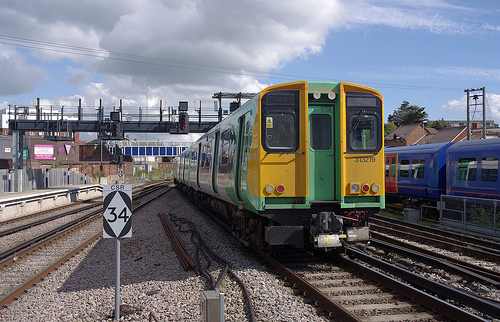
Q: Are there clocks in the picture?
A: No, there are no clocks.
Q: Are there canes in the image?
A: No, there are no canes.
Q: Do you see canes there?
A: No, there are no canes.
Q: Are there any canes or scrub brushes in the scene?
A: No, there are no canes or scrub brushes.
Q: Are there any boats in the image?
A: No, there are no boats.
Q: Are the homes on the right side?
A: Yes, the homes are on the right of the image.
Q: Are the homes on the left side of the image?
A: No, the homes are on the right of the image.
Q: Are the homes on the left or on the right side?
A: The homes are on the right of the image.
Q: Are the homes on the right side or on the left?
A: The homes are on the right of the image.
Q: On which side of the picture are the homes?
A: The homes are on the right of the image.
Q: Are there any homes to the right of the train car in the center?
A: Yes, there are homes to the right of the train car.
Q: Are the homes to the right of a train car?
A: Yes, the homes are to the right of a train car.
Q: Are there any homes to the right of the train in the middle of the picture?
A: Yes, there are homes to the right of the train.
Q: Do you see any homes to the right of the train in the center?
A: Yes, there are homes to the right of the train.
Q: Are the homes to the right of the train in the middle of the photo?
A: Yes, the homes are to the right of the train.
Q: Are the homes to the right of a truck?
A: No, the homes are to the right of the train.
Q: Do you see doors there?
A: Yes, there is a door.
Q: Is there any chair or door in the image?
A: Yes, there is a door.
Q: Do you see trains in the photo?
A: Yes, there is a train.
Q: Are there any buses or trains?
A: Yes, there is a train.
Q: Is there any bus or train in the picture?
A: Yes, there is a train.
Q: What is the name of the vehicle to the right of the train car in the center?
A: The vehicle is a train.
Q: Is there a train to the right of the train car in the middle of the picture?
A: Yes, there is a train to the right of the train car.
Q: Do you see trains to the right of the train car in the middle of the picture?
A: Yes, there is a train to the right of the train car.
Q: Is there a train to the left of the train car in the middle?
A: No, the train is to the right of the train car.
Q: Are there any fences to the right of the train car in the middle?
A: No, there is a train to the right of the train car.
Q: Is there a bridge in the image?
A: Yes, there is a bridge.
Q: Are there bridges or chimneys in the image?
A: Yes, there is a bridge.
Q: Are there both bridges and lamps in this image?
A: No, there is a bridge but no lamps.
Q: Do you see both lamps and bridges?
A: No, there is a bridge but no lamps.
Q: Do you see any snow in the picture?
A: Yes, there is snow.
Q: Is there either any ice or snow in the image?
A: Yes, there is snow.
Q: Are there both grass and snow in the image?
A: No, there is snow but no grass.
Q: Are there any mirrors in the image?
A: No, there are no mirrors.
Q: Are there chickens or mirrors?
A: No, there are no mirrors or chickens.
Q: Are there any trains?
A: Yes, there is a train.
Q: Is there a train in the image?
A: Yes, there is a train.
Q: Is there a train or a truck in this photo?
A: Yes, there is a train.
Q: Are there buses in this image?
A: No, there are no buses.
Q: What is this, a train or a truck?
A: This is a train.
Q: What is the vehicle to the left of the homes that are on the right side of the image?
A: The vehicle is a train.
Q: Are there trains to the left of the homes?
A: Yes, there is a train to the left of the homes.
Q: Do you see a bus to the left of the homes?
A: No, there is a train to the left of the homes.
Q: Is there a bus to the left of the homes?
A: No, there is a train to the left of the homes.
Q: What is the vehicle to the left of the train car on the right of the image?
A: The vehicle is a train.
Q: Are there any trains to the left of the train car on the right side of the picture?
A: Yes, there is a train to the left of the train car.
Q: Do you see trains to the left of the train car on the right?
A: Yes, there is a train to the left of the train car.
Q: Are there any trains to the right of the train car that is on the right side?
A: No, the train is to the left of the train car.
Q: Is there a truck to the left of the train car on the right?
A: No, there is a train to the left of the train car.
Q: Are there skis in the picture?
A: No, there are no skis.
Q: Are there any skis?
A: No, there are no skis.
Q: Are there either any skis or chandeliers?
A: No, there are no skis or chandeliers.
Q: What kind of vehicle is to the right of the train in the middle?
A: The vehicle is a train car.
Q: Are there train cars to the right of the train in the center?
A: Yes, there is a train car to the right of the train.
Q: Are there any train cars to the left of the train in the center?
A: No, the train car is to the right of the train.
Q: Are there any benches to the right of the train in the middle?
A: No, there is a train car to the right of the train.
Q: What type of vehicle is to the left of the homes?
A: The vehicle is a train car.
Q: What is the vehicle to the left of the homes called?
A: The vehicle is a train car.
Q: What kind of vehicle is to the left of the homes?
A: The vehicle is a train car.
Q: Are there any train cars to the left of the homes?
A: Yes, there is a train car to the left of the homes.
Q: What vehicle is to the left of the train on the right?
A: The vehicle is a train car.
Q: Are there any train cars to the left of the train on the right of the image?
A: Yes, there is a train car to the left of the train.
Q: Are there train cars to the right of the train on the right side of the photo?
A: No, the train car is to the left of the train.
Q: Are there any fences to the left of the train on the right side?
A: No, there is a train car to the left of the train.